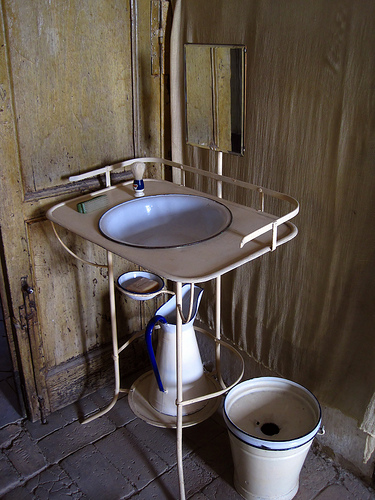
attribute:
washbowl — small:
[92, 189, 235, 251]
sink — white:
[94, 182, 246, 263]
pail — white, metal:
[216, 367, 334, 477]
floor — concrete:
[53, 424, 149, 494]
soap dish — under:
[118, 269, 166, 301]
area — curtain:
[220, 80, 373, 287]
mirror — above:
[181, 43, 245, 154]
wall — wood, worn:
[2, 0, 175, 431]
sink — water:
[98, 191, 234, 245]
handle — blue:
[128, 297, 184, 390]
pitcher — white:
[106, 268, 235, 482]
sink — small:
[72, 154, 286, 284]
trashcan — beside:
[215, 378, 330, 499]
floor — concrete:
[61, 401, 185, 499]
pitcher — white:
[146, 282, 212, 416]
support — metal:
[79, 397, 120, 427]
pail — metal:
[187, 377, 364, 482]